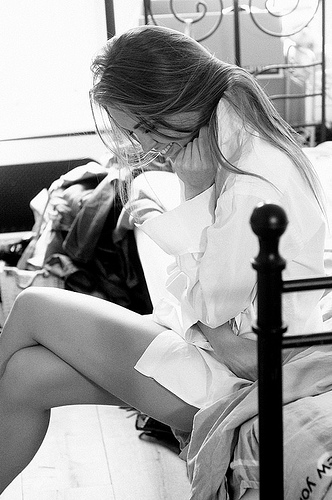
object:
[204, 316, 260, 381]
hand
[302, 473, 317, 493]
letter "y"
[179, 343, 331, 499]
blanket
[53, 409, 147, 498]
floor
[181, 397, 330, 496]
sheets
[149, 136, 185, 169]
smile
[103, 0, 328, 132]
headboard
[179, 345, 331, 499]
sheets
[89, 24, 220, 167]
head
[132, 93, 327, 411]
shirt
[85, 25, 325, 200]
hair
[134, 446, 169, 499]
ground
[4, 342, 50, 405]
knee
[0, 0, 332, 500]
bed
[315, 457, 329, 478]
letters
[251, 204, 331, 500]
metal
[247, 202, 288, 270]
round part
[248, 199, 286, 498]
bed post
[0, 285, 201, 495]
legs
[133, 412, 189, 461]
shoes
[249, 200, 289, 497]
post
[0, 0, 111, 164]
window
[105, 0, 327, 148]
bed frame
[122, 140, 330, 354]
sheets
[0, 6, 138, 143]
light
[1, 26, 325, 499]
woman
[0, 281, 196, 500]
thigh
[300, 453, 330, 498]
new york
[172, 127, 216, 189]
hand